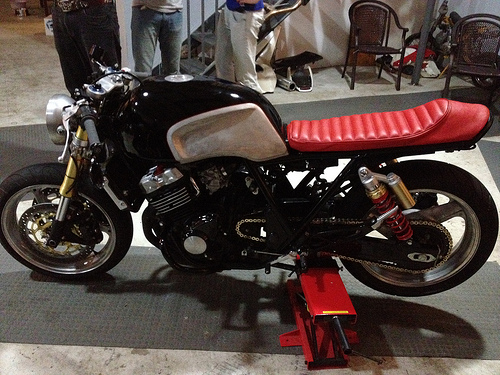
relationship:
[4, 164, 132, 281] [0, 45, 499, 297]
front wheel of black motorcycle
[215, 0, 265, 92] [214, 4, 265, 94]
person wearing pants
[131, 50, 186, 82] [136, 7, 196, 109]
person with jean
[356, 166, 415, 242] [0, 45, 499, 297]
absorption mounted on black motorcycle